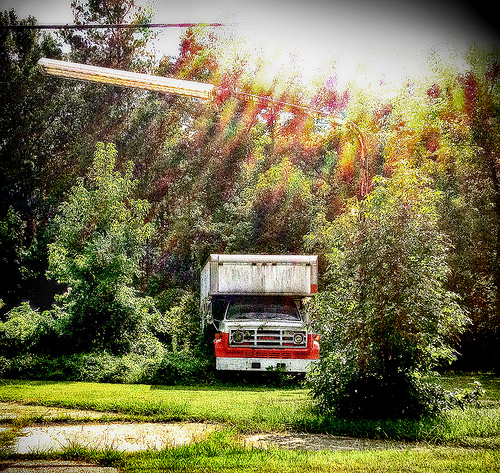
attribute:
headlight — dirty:
[224, 330, 305, 347]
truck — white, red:
[198, 253, 320, 386]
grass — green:
[17, 381, 307, 431]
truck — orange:
[195, 249, 334, 387]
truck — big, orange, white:
[187, 237, 330, 392]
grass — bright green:
[123, 393, 194, 438]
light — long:
[36, 54, 214, 103]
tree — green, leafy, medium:
[303, 156, 485, 423]